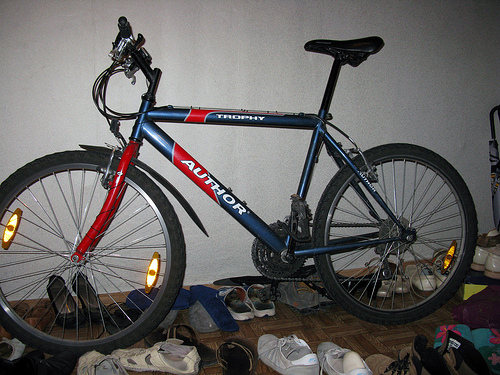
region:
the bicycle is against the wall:
[0, 15, 470, 342]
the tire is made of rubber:
[3, 148, 188, 351]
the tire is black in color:
[6, 144, 185, 361]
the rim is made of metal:
[3, 160, 174, 344]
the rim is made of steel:
[7, 165, 177, 345]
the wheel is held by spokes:
[8, 170, 172, 345]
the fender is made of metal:
[81, 137, 214, 242]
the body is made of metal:
[70, 81, 408, 283]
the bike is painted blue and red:
[81, 90, 404, 300]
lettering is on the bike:
[180, 154, 251, 220]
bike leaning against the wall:
[2, 11, 471, 351]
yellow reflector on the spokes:
[433, 240, 460, 275]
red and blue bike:
[3, 8, 481, 350]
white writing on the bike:
[175, 155, 255, 220]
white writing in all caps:
[215, 110, 268, 124]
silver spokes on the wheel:
[0, 153, 183, 351]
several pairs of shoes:
[0, 262, 497, 372]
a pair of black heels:
[46, 265, 112, 335]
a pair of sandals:
[146, 318, 270, 374]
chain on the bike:
[266, 270, 405, 288]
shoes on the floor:
[42, 264, 493, 366]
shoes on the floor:
[167, 272, 354, 371]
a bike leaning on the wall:
[10, 20, 463, 357]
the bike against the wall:
[0, 15, 476, 350]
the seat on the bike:
[305, 35, 385, 68]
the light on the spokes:
[1, 208, 23, 249]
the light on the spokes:
[144, 251, 160, 293]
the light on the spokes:
[440, 239, 455, 274]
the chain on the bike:
[250, 221, 392, 281]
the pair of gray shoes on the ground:
[257, 333, 373, 374]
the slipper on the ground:
[215, 335, 257, 373]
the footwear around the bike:
[0, 227, 498, 374]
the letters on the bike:
[180, 159, 246, 214]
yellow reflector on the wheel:
[431, 238, 460, 273]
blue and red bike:
[0, 11, 481, 361]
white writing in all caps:
[211, 108, 265, 123]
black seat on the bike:
[299, 25, 389, 68]